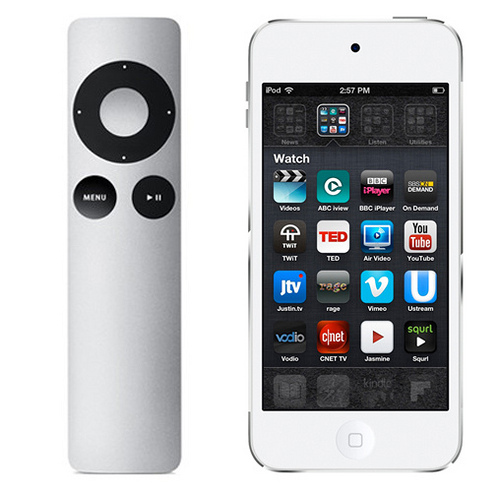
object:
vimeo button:
[360, 269, 395, 305]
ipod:
[247, 15, 464, 471]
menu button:
[72, 174, 117, 221]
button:
[316, 319, 350, 353]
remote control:
[67, 16, 183, 474]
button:
[130, 174, 177, 221]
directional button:
[72, 59, 176, 165]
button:
[360, 319, 395, 353]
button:
[403, 269, 437, 304]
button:
[273, 270, 307, 302]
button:
[273, 168, 308, 205]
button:
[316, 169, 352, 204]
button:
[360, 169, 395, 206]